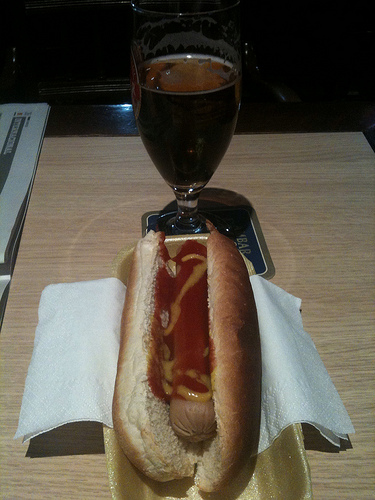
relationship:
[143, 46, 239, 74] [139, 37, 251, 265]
foam in glass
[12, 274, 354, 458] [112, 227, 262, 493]
napkin under hot dog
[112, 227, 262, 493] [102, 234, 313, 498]
hot dog on tray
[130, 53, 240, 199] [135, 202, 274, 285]
beer on coaster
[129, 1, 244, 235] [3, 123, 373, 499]
glass on table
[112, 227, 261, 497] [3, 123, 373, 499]
hot dog on table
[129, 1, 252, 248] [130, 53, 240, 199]
glass of beer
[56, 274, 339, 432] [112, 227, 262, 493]
napkin under hot dog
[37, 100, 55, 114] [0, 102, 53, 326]
corner of newspaper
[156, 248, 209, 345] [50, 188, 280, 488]
cheese on hot dog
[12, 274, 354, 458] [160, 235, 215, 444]
napkin under hotdog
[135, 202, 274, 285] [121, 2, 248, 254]
coaster under glass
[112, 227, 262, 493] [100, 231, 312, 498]
hot dog in bowl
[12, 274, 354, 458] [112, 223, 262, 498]
napkin under bun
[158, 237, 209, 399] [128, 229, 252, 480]
ketchup on hot dog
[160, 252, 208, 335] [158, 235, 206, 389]
mustard on ketchup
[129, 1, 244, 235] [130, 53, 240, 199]
glass of beer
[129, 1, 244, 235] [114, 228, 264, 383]
glass in front of hot dog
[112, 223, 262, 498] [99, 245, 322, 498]
bun on cup